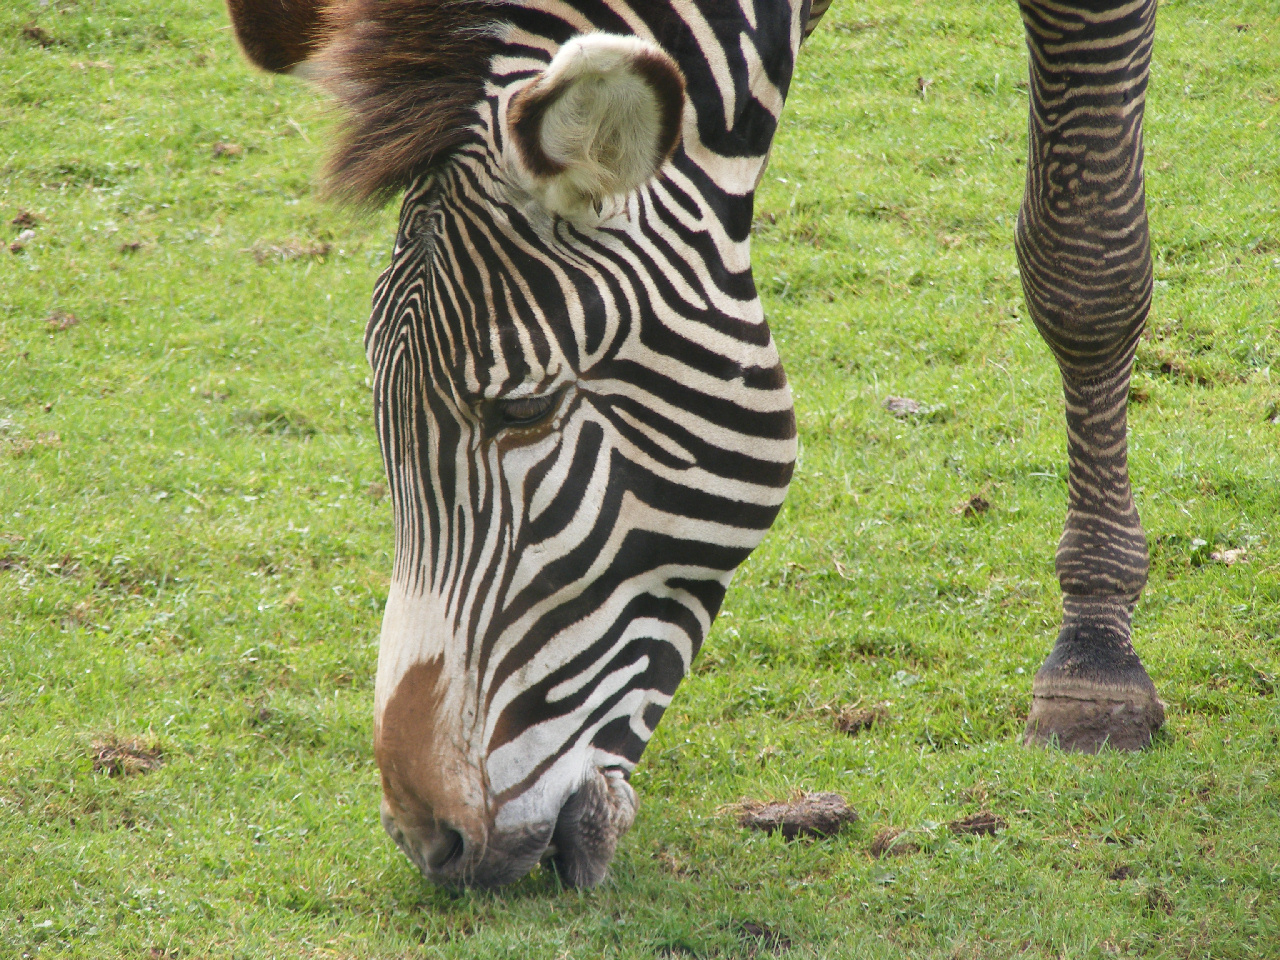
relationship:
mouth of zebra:
[368, 713, 626, 952] [256, 264, 902, 960]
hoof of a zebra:
[1009, 650, 1174, 755] [177, 257, 1228, 960]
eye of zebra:
[498, 390, 564, 431] [39, 2, 1244, 918]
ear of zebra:
[486, 34, 683, 215] [39, 2, 1244, 918]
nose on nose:
[374, 664, 481, 897] [374, 668, 646, 926]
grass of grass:
[758, 796, 857, 835] [735, 772, 876, 862]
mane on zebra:
[309, 3, 478, 207] [361, 37, 798, 899]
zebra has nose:
[361, 37, 798, 899] [339, 647, 483, 896]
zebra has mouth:
[361, 37, 798, 899] [519, 765, 626, 911]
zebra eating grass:
[361, 37, 798, 899] [37, 46, 1219, 923]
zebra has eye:
[361, 37, 798, 899] [444, 344, 597, 472]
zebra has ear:
[361, 37, 798, 899] [486, 30, 688, 227]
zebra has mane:
[361, 37, 798, 899] [309, 3, 478, 207]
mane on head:
[309, 3, 478, 207] [337, 2, 800, 923]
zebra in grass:
[243, 23, 845, 867] [652, 407, 1056, 923]